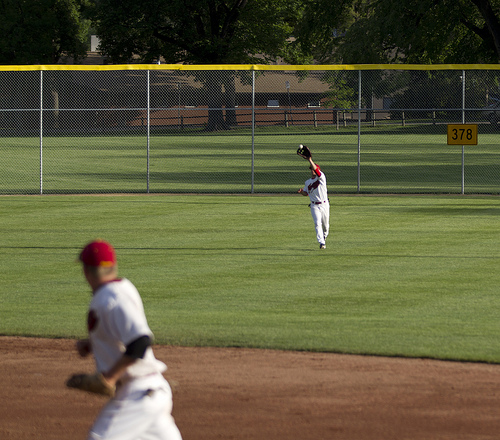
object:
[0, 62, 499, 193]
fence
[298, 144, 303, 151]
ball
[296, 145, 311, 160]
glove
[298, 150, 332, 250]
man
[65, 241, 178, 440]
player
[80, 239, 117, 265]
cap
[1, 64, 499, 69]
yellow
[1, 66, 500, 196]
chain link fence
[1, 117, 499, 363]
grass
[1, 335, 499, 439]
dirt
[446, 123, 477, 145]
number sign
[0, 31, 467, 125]
building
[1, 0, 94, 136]
tree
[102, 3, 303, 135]
tree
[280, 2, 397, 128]
tree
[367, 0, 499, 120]
tree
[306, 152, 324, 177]
arm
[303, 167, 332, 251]
uniform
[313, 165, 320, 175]
baseball cap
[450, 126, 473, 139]
numbers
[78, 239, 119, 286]
head